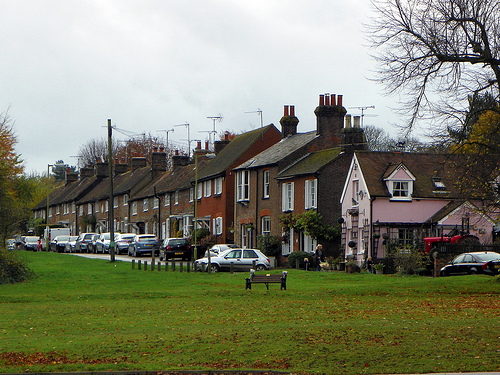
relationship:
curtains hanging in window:
[393, 182, 409, 196] [382, 168, 420, 202]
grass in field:
[7, 286, 499, 370] [14, 246, 472, 372]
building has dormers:
[340, 149, 500, 271] [363, 218, 469, 265]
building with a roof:
[340, 149, 500, 271] [340, 145, 500, 202]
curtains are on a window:
[393, 183, 409, 192] [391, 180, 408, 197]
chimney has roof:
[314, 83, 347, 140] [313, 95, 348, 130]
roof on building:
[313, 95, 348, 130] [271, 96, 352, 265]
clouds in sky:
[129, 20, 169, 48] [2, 3, 481, 151]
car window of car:
[225, 250, 241, 259] [194, 248, 270, 270]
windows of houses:
[191, 149, 366, 221] [272, 110, 366, 265]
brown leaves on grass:
[0, 285, 499, 375] [1, 251, 498, 373]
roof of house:
[355, 148, 499, 200] [338, 146, 498, 269]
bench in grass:
[245, 269, 288, 290] [1, 251, 498, 373]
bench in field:
[245, 269, 288, 290] [35, 284, 208, 351]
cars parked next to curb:
[67, 193, 372, 335] [72, 253, 139, 265]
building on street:
[129, 134, 231, 260] [87, 243, 173, 258]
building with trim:
[340, 149, 500, 271] [316, 143, 449, 329]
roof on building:
[224, 128, 315, 176] [193, 105, 297, 257]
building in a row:
[193, 105, 297, 257] [42, 189, 377, 260]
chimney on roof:
[314, 92, 349, 146] [234, 127, 320, 172]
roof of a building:
[234, 127, 320, 172] [230, 92, 347, 259]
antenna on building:
[154, 108, 265, 160] [193, 109, 286, 247]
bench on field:
[246, 264, 292, 295] [41, 282, 490, 357]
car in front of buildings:
[159, 237, 191, 261] [62, 90, 474, 277]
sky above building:
[72, 18, 207, 82] [236, 93, 366, 259]